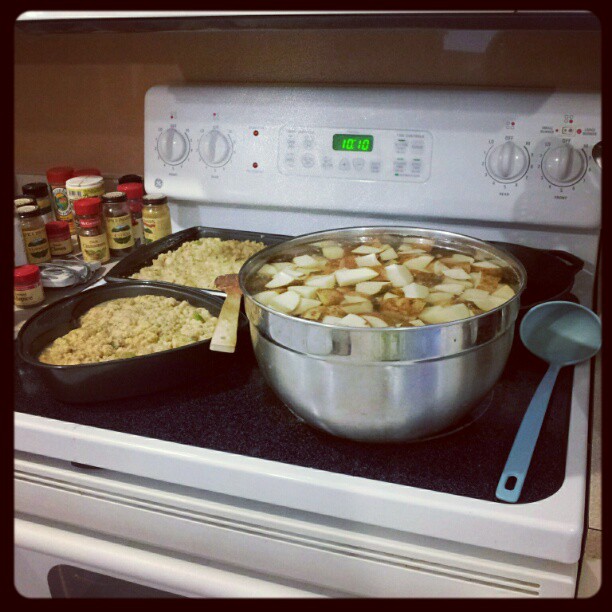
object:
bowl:
[239, 224, 525, 441]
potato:
[333, 264, 379, 287]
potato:
[403, 281, 427, 299]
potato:
[265, 269, 292, 288]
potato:
[442, 266, 469, 280]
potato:
[293, 254, 319, 266]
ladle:
[496, 300, 602, 504]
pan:
[15, 282, 248, 404]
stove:
[14, 0, 601, 602]